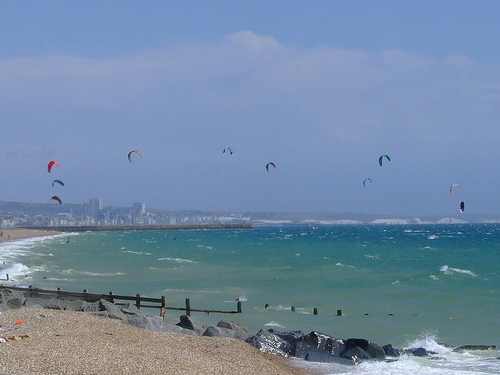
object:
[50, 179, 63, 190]
kite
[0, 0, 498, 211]
sky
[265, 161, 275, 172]
kite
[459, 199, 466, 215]
kite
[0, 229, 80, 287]
waves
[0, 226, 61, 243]
ashore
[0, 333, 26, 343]
person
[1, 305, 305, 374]
sand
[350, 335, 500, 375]
waves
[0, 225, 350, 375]
beach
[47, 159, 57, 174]
kite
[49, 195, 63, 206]
kite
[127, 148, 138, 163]
kite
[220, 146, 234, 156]
kite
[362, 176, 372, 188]
kite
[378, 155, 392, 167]
kite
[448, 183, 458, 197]
kite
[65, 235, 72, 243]
people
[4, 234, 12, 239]
people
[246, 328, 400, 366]
rocks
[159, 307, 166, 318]
person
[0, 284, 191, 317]
posts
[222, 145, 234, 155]
kites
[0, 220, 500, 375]
ocean